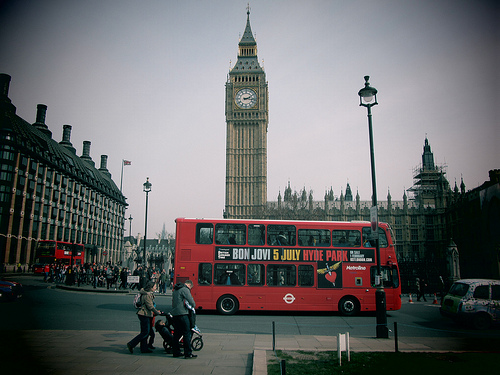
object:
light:
[458, 302, 463, 312]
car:
[441, 279, 500, 324]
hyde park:
[302, 250, 348, 261]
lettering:
[303, 250, 348, 261]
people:
[127, 281, 163, 354]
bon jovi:
[232, 248, 271, 261]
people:
[171, 280, 198, 359]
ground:
[0, 277, 500, 375]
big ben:
[223, 2, 269, 219]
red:
[307, 290, 327, 308]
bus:
[33, 240, 84, 276]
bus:
[175, 217, 402, 316]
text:
[233, 248, 348, 261]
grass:
[266, 352, 500, 375]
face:
[234, 87, 259, 109]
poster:
[215, 246, 375, 262]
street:
[0, 283, 497, 375]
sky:
[0, 0, 213, 141]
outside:
[0, 3, 500, 375]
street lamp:
[357, 74, 389, 339]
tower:
[225, 1, 267, 219]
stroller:
[154, 310, 203, 353]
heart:
[325, 271, 337, 282]